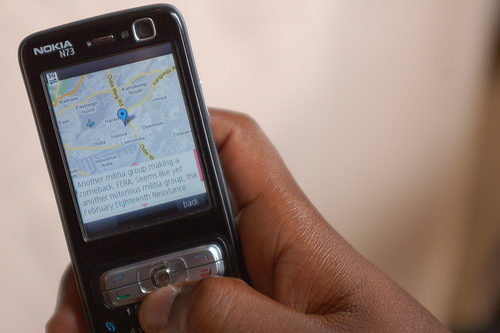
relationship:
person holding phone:
[27, 103, 471, 330] [11, 1, 254, 330]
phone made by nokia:
[11, 1, 254, 330] [22, 33, 83, 66]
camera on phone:
[129, 13, 160, 44] [11, 1, 254, 330]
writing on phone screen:
[71, 152, 201, 217] [40, 45, 212, 226]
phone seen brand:
[11, 1, 254, 330] [22, 33, 83, 66]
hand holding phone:
[27, 103, 471, 330] [11, 1, 254, 330]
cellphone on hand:
[11, 1, 254, 330] [27, 103, 471, 330]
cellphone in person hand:
[11, 1, 254, 330] [27, 103, 471, 330]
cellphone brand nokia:
[11, 1, 254, 330] [22, 33, 83, 66]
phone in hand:
[11, 1, 254, 330] [27, 103, 471, 330]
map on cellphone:
[40, 45, 212, 226] [11, 1, 254, 330]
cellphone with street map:
[11, 1, 254, 330] [40, 45, 212, 226]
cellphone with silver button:
[11, 1, 254, 330] [149, 265, 178, 289]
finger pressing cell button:
[133, 271, 316, 332] [144, 258, 181, 290]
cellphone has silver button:
[11, 1, 254, 330] [149, 265, 178, 289]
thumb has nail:
[133, 271, 316, 332] [135, 280, 185, 329]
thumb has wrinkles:
[133, 271, 316, 332] [180, 275, 290, 329]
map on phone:
[40, 45, 212, 226] [11, 1, 254, 330]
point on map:
[115, 104, 130, 126] [40, 45, 212, 226]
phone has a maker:
[11, 1, 254, 330] [115, 104, 130, 126]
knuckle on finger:
[186, 274, 229, 330] [133, 271, 316, 332]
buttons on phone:
[96, 243, 233, 312] [11, 1, 254, 330]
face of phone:
[40, 45, 212, 226] [11, 1, 254, 330]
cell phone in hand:
[11, 1, 254, 330] [27, 103, 471, 330]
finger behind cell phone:
[203, 98, 301, 253] [11, 1, 254, 330]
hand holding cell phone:
[27, 103, 471, 330] [11, 1, 254, 330]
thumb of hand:
[133, 271, 316, 332] [27, 103, 471, 330]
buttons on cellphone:
[96, 243, 233, 312] [11, 1, 254, 330]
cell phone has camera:
[11, 1, 254, 330] [129, 13, 160, 44]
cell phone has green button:
[11, 1, 254, 330] [108, 286, 136, 305]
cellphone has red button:
[11, 1, 254, 330] [195, 266, 215, 282]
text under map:
[71, 152, 201, 217] [48, 51, 185, 167]